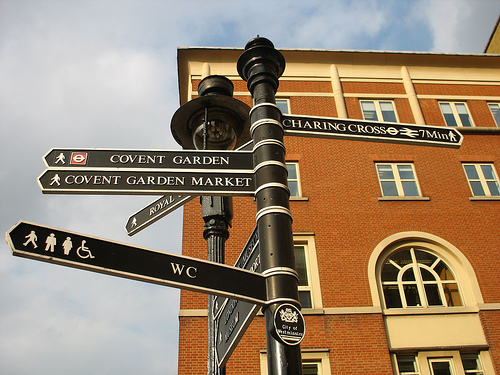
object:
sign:
[282, 114, 464, 149]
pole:
[236, 36, 305, 375]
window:
[380, 248, 464, 310]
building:
[174, 19, 500, 375]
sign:
[274, 303, 306, 346]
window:
[284, 162, 302, 197]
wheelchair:
[76, 246, 90, 259]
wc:
[170, 262, 197, 278]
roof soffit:
[179, 47, 496, 69]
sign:
[123, 138, 256, 236]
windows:
[486, 102, 500, 128]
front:
[181, 50, 498, 373]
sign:
[36, 169, 257, 197]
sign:
[42, 147, 254, 170]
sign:
[124, 195, 197, 237]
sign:
[4, 218, 266, 306]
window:
[375, 162, 422, 197]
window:
[359, 99, 400, 123]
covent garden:
[110, 155, 230, 166]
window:
[437, 101, 475, 127]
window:
[291, 243, 313, 309]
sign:
[211, 227, 264, 369]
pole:
[197, 192, 233, 375]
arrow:
[36, 168, 256, 197]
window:
[461, 163, 500, 198]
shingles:
[268, 50, 463, 88]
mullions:
[382, 248, 465, 309]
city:
[0, 0, 500, 375]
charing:
[282, 119, 346, 131]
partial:
[124, 194, 196, 236]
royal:
[149, 196, 174, 216]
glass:
[465, 165, 480, 180]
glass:
[455, 103, 473, 126]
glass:
[361, 102, 378, 121]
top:
[197, 75, 233, 97]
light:
[170, 75, 252, 150]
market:
[191, 176, 252, 186]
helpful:
[37, 147, 258, 197]